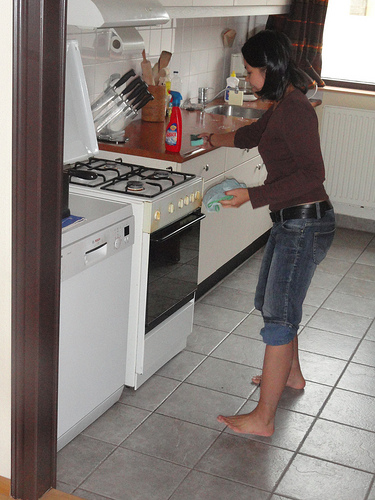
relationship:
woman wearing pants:
[211, 21, 337, 444] [249, 198, 339, 349]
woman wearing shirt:
[211, 21, 337, 444] [233, 85, 330, 207]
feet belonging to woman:
[217, 411, 277, 440] [211, 21, 337, 444]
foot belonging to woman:
[250, 370, 306, 389] [211, 21, 337, 444]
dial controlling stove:
[153, 209, 161, 220] [62, 38, 206, 391]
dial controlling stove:
[168, 201, 174, 214] [62, 38, 206, 391]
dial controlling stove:
[176, 197, 184, 209] [62, 38, 206, 391]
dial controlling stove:
[182, 192, 190, 205] [62, 38, 206, 391]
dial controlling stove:
[188, 192, 196, 203] [62, 38, 206, 391]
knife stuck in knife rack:
[89, 66, 136, 112] [90, 87, 137, 143]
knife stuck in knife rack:
[93, 75, 142, 122] [90, 87, 137, 143]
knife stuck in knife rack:
[93, 79, 148, 129] [90, 87, 137, 143]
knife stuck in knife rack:
[120, 93, 154, 129] [90, 87, 137, 143]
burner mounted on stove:
[65, 155, 142, 189] [62, 38, 206, 391]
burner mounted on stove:
[79, 155, 142, 178] [62, 38, 206, 391]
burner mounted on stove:
[100, 172, 169, 199] [62, 38, 206, 391]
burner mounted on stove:
[101, 164, 196, 199] [62, 38, 206, 391]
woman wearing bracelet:
[211, 21, 337, 444] [202, 131, 214, 150]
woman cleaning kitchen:
[211, 21, 337, 444] [79, 7, 342, 331]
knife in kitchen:
[90, 69, 136, 113] [73, 1, 300, 323]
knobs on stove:
[145, 183, 226, 217] [60, 132, 219, 395]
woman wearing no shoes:
[211, 21, 337, 444] [215, 365, 332, 472]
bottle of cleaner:
[158, 92, 200, 174] [163, 87, 183, 153]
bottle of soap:
[223, 68, 241, 104] [214, 62, 243, 110]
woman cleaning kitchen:
[211, 21, 337, 444] [53, 0, 323, 319]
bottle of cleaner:
[214, 69, 250, 113] [220, 71, 260, 121]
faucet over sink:
[183, 75, 234, 104] [184, 81, 271, 138]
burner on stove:
[101, 164, 196, 199] [76, 158, 186, 215]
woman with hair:
[236, 21, 332, 401] [228, 31, 320, 124]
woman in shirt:
[211, 21, 337, 444] [226, 88, 335, 206]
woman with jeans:
[211, 21, 337, 444] [251, 197, 344, 342]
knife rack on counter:
[90, 84, 137, 143] [110, 104, 256, 159]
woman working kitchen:
[211, 21, 337, 444] [28, 5, 354, 498]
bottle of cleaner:
[162, 88, 184, 153] [163, 87, 186, 150]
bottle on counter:
[162, 88, 184, 153] [102, 109, 247, 159]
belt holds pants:
[270, 198, 331, 221] [254, 200, 335, 343]